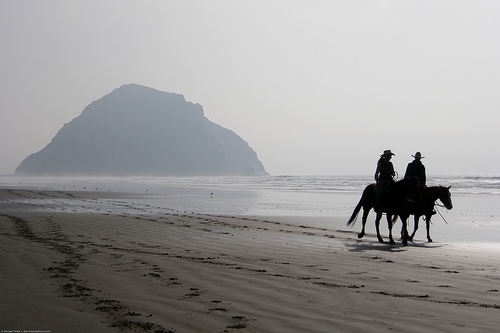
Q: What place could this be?
A: It is a beach.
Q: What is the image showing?
A: It is showing a beach.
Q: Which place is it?
A: It is a beach.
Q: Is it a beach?
A: Yes, it is a beach.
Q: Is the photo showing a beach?
A: Yes, it is showing a beach.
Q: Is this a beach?
A: Yes, it is a beach.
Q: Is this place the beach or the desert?
A: It is the beach.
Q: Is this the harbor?
A: No, it is the beach.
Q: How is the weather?
A: It is foggy.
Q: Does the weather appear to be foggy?
A: Yes, it is foggy.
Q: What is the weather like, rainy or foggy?
A: It is foggy.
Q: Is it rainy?
A: No, it is foggy.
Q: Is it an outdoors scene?
A: Yes, it is outdoors.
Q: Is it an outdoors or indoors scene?
A: It is outdoors.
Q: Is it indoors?
A: No, it is outdoors.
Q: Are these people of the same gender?
A: No, they are both male and female.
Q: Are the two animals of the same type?
A: Yes, all the animals are horses.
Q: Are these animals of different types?
A: No, all the animals are horses.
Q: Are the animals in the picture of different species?
A: No, all the animals are horses.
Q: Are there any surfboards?
A: No, there are no surfboards.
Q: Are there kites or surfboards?
A: No, there are no surfboards or kites.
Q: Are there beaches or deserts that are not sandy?
A: No, there is a beach but it is sandy.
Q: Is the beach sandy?
A: Yes, the beach is sandy.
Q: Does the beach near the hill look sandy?
A: Yes, the beach is sandy.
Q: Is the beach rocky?
A: No, the beach is sandy.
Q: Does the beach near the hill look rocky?
A: No, the beach is sandy.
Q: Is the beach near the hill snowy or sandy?
A: The beach is sandy.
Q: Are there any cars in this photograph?
A: No, there are no cars.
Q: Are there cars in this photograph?
A: No, there are no cars.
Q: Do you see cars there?
A: No, there are no cars.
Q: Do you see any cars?
A: No, there are no cars.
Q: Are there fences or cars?
A: No, there are no cars or fences.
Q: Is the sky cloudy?
A: Yes, the sky is cloudy.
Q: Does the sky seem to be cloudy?
A: Yes, the sky is cloudy.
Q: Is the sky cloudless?
A: No, the sky is cloudy.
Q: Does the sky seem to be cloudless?
A: No, the sky is cloudy.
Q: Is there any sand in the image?
A: Yes, there is sand.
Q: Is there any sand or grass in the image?
A: Yes, there is sand.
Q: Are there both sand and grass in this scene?
A: No, there is sand but no grass.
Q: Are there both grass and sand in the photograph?
A: No, there is sand but no grass.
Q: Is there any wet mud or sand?
A: Yes, there is wet sand.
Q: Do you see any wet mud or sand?
A: Yes, there is wet sand.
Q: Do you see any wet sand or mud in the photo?
A: Yes, there is wet sand.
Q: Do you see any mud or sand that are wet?
A: Yes, the sand is wet.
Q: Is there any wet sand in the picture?
A: Yes, there is wet sand.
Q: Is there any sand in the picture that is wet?
A: Yes, there is sand that is wet.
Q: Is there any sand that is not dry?
A: Yes, there is wet sand.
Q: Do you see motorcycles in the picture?
A: No, there are no motorcycles.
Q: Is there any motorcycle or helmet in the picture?
A: No, there are no motorcycles or helmets.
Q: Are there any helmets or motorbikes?
A: No, there are no motorbikes or helmets.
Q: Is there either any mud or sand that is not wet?
A: No, there is sand but it is wet.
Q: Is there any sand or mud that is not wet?
A: No, there is sand but it is wet.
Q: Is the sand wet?
A: Yes, the sand is wet.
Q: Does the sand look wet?
A: Yes, the sand is wet.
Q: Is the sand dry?
A: No, the sand is wet.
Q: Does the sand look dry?
A: No, the sand is wet.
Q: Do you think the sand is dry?
A: No, the sand is wet.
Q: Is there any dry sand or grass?
A: No, there is sand but it is wet.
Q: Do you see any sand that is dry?
A: No, there is sand but it is wet.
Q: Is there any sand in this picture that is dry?
A: No, there is sand but it is wet.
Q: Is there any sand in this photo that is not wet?
A: No, there is sand but it is wet.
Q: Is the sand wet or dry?
A: The sand is wet.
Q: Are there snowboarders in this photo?
A: No, there are no snowboarders.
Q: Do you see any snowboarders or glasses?
A: No, there are no snowboarders or glasses.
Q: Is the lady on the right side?
A: Yes, the lady is on the right of the image.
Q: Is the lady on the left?
A: No, the lady is on the right of the image.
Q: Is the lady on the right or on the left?
A: The lady is on the right of the image.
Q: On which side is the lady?
A: The lady is on the right of the image.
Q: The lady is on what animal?
A: The lady is on the horse.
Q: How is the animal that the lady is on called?
A: The animal is a horse.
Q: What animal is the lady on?
A: The lady is on the horse.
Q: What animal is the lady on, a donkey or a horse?
A: The lady is on a horse.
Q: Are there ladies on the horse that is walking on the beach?
A: Yes, there is a lady on the horse.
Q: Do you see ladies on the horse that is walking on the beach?
A: Yes, there is a lady on the horse.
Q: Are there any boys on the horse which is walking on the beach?
A: No, there is a lady on the horse.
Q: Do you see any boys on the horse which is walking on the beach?
A: No, there is a lady on the horse.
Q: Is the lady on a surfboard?
A: No, the lady is on the horse.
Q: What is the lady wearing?
A: The lady is wearing a hat.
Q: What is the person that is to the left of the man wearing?
A: The lady is wearing a hat.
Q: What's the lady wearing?
A: The lady is wearing a hat.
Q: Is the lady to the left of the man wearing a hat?
A: Yes, the lady is wearing a hat.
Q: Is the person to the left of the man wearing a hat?
A: Yes, the lady is wearing a hat.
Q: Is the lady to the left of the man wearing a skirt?
A: No, the lady is wearing a hat.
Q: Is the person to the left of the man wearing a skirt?
A: No, the lady is wearing a hat.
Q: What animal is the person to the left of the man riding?
A: The lady is riding a horse.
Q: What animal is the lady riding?
A: The lady is riding a horse.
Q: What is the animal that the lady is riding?
A: The animal is a horse.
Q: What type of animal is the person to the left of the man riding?
A: The lady is riding a horse.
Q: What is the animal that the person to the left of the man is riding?
A: The animal is a horse.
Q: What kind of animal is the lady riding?
A: The lady is riding a horse.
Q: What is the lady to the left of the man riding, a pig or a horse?
A: The lady is riding a horse.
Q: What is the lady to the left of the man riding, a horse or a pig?
A: The lady is riding a horse.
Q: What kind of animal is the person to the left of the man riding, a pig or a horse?
A: The lady is riding a horse.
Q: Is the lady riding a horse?
A: Yes, the lady is riding a horse.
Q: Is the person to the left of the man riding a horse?
A: Yes, the lady is riding a horse.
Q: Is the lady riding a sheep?
A: No, the lady is riding a horse.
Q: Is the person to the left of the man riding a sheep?
A: No, the lady is riding a horse.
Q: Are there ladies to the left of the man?
A: Yes, there is a lady to the left of the man.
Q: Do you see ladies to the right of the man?
A: No, the lady is to the left of the man.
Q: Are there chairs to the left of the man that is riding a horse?
A: No, there is a lady to the left of the man.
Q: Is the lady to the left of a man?
A: Yes, the lady is to the left of a man.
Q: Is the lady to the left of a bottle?
A: No, the lady is to the left of a man.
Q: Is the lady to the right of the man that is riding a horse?
A: No, the lady is to the left of the man.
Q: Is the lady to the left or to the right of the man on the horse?
A: The lady is to the left of the man.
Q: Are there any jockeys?
A: No, there are no jockeys.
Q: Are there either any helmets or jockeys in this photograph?
A: No, there are no jockeys or helmets.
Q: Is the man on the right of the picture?
A: Yes, the man is on the right of the image.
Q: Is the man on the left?
A: No, the man is on the right of the image.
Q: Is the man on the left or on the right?
A: The man is on the right of the image.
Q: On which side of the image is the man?
A: The man is on the right of the image.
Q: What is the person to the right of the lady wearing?
A: The man is wearing a hat.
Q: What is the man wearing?
A: The man is wearing a hat.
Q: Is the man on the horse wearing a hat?
A: Yes, the man is wearing a hat.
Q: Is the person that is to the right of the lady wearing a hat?
A: Yes, the man is wearing a hat.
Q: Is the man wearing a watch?
A: No, the man is wearing a hat.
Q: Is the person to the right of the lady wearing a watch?
A: No, the man is wearing a hat.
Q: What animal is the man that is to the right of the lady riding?
A: The man is riding a horse.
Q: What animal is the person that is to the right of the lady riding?
A: The man is riding a horse.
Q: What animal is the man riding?
A: The man is riding a horse.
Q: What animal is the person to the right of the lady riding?
A: The man is riding a horse.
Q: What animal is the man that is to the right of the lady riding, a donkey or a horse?
A: The man is riding a horse.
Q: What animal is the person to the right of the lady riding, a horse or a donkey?
A: The man is riding a horse.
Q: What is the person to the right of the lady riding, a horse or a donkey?
A: The man is riding a horse.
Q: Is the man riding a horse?
A: Yes, the man is riding a horse.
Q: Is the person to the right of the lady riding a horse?
A: Yes, the man is riding a horse.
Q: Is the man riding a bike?
A: No, the man is riding a horse.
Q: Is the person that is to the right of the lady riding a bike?
A: No, the man is riding a horse.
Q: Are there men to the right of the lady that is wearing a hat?
A: Yes, there is a man to the right of the lady.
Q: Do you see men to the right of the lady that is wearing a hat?
A: Yes, there is a man to the right of the lady.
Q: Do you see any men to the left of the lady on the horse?
A: No, the man is to the right of the lady.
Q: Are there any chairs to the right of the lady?
A: No, there is a man to the right of the lady.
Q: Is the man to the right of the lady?
A: Yes, the man is to the right of the lady.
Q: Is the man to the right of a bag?
A: No, the man is to the right of the lady.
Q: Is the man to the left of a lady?
A: No, the man is to the right of a lady.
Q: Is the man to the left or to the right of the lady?
A: The man is to the right of the lady.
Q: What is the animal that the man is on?
A: The animal is a horse.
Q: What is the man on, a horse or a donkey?
A: The man is on a horse.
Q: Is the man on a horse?
A: Yes, the man is on a horse.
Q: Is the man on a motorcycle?
A: No, the man is on a horse.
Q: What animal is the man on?
A: The man is on the horse.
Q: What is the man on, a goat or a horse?
A: The man is on a horse.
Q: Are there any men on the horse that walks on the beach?
A: Yes, there is a man on the horse.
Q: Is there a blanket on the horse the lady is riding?
A: No, there is a man on the horse.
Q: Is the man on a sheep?
A: No, the man is on a horse.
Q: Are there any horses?
A: Yes, there is a horse.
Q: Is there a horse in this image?
A: Yes, there is a horse.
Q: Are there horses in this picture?
A: Yes, there is a horse.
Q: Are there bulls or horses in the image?
A: Yes, there is a horse.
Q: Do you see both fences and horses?
A: No, there is a horse but no fences.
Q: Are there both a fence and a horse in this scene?
A: No, there is a horse but no fences.